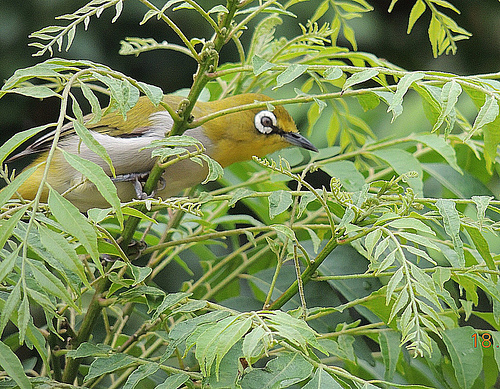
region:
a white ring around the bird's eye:
[253, 110, 277, 135]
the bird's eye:
[260, 114, 273, 126]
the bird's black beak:
[282, 126, 322, 153]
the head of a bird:
[201, 90, 321, 182]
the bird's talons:
[98, 164, 174, 194]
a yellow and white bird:
[6, 90, 316, 264]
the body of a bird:
[8, 93, 211, 216]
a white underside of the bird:
[47, 105, 207, 216]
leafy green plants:
[0, 0, 499, 387]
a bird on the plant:
[0, 93, 322, 282]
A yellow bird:
[6, 91, 368, 225]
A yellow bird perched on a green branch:
[3, 82, 329, 217]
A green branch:
[288, 202, 373, 323]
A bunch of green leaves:
[100, 218, 457, 364]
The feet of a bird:
[98, 162, 183, 205]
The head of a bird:
[222, 90, 320, 155]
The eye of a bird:
[252, 109, 276, 133]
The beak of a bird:
[283, 126, 323, 161]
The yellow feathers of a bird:
[198, 100, 245, 158]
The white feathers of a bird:
[85, 133, 163, 170]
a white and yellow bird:
[29, 66, 321, 201]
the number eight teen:
[465, 325, 497, 350]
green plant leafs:
[170, 280, 327, 382]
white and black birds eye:
[253, 106, 277, 136]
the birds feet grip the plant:
[100, 151, 170, 208]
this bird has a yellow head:
[217, 94, 322, 166]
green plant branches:
[25, 2, 127, 67]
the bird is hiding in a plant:
[0, 51, 305, 246]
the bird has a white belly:
[19, 86, 209, 178]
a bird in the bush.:
[35, 13, 440, 323]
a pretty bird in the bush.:
[30, 11, 430, 331]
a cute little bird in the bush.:
[0, 15, 421, 315]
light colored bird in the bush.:
[10, 20, 385, 350]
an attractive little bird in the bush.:
[31, 10, 387, 325]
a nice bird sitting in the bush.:
[25, 12, 430, 337]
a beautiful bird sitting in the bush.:
[45, 21, 355, 297]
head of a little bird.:
[225, 80, 322, 181]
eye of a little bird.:
[255, 105, 275, 136]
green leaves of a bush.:
[188, 215, 473, 370]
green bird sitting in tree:
[9, 84, 334, 246]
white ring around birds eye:
[246, 105, 284, 147]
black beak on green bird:
[274, 121, 334, 162]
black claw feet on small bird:
[96, 166, 195, 203]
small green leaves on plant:
[325, 178, 481, 372]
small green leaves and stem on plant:
[13, 223, 127, 387]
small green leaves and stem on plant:
[253, 243, 368, 386]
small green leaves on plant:
[128, 4, 384, 90]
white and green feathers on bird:
[12, 97, 144, 168]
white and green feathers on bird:
[117, 86, 227, 188]